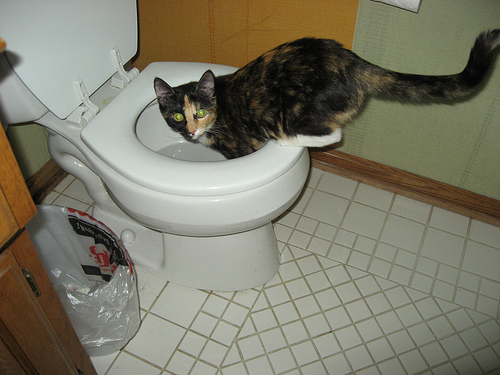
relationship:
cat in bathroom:
[138, 33, 496, 154] [19, 154, 481, 354]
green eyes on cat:
[164, 95, 214, 126] [129, 33, 471, 178]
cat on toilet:
[138, 33, 496, 154] [0, 4, 312, 290]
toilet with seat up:
[0, 4, 312, 290] [78, 58, 303, 198]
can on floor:
[33, 200, 153, 342] [36, 162, 496, 371]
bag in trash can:
[20, 203, 143, 357] [30, 189, 167, 359]